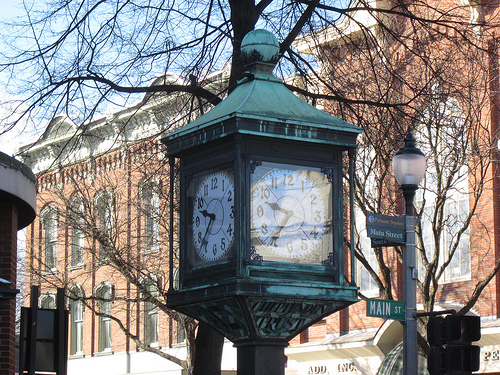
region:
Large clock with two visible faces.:
[158, 29, 356, 374]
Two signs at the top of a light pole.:
[365, 210, 407, 243]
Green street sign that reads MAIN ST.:
[365, 296, 405, 319]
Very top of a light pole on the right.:
[389, 124, 429, 190]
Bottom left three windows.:
[33, 280, 117, 357]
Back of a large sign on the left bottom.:
[17, 307, 67, 373]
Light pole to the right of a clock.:
[390, 124, 427, 374]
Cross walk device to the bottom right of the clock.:
[427, 314, 484, 374]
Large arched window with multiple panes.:
[403, 93, 470, 285]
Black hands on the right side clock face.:
[262, 201, 294, 250]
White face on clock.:
[176, 170, 291, 321]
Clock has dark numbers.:
[194, 205, 266, 322]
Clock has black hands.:
[181, 200, 269, 286]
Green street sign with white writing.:
[346, 277, 437, 353]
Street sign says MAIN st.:
[345, 276, 405, 318]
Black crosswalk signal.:
[425, 310, 474, 367]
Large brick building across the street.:
[55, 182, 252, 372]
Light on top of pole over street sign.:
[380, 143, 438, 215]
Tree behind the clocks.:
[138, 107, 427, 357]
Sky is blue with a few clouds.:
[12, 53, 111, 103]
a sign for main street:
[362, 287, 427, 324]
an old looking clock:
[150, 34, 352, 373]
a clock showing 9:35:
[173, 159, 238, 290]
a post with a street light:
[360, 124, 435, 366]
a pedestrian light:
[408, 296, 482, 373]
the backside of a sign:
[1, 268, 83, 371]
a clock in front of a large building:
[18, 2, 495, 373]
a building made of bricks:
[2, 120, 176, 365]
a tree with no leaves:
[15, 0, 497, 122]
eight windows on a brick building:
[38, 191, 178, 371]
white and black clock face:
[182, 174, 238, 268]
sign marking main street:
[363, 294, 413, 322]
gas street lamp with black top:
[390, 132, 428, 218]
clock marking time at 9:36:
[249, 166, 336, 266]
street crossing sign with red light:
[423, 310, 483, 373]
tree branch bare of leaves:
[20, 12, 190, 90]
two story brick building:
[30, 118, 152, 311]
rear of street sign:
[13, 285, 72, 374]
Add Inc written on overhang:
[292, 356, 363, 373]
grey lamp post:
[399, 205, 419, 372]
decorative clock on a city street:
[145, 21, 392, 363]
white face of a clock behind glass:
[257, 169, 338, 263]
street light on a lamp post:
[386, 118, 441, 198]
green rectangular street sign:
[362, 293, 407, 328]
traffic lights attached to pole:
[425, 303, 488, 373]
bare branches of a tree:
[4, 3, 206, 106]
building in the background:
[34, 91, 171, 368]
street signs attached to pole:
[361, 207, 409, 258]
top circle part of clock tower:
[235, 22, 287, 73]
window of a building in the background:
[86, 274, 121, 354]